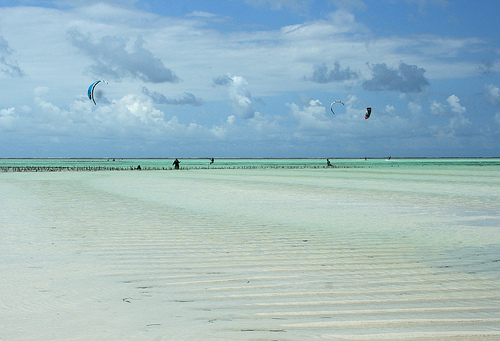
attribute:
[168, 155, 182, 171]
people — background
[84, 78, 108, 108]
para kite — pulling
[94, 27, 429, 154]
clouds — large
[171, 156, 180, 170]
person — watching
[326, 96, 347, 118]
kite — bending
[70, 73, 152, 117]
kite — flying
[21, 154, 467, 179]
water — aqua green, blue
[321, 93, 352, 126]
kite — curved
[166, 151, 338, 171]
people — scattered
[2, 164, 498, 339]
sand — white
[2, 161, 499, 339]
beach — large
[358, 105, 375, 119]
kite — black, red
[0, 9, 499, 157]
clouds — rolling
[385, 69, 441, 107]
sky — blue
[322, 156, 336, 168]
person — background, wearing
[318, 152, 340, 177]
person — running